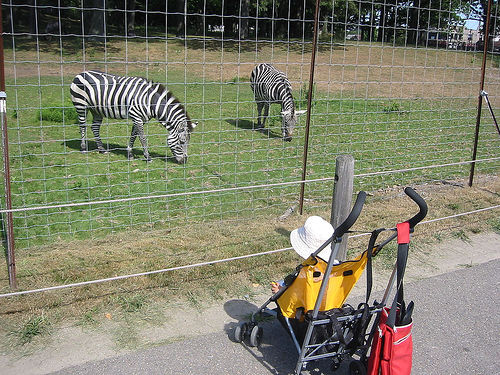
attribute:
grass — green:
[3, 73, 498, 256]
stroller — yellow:
[234, 184, 430, 373]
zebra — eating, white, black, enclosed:
[71, 72, 195, 165]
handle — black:
[401, 186, 427, 226]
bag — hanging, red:
[366, 222, 413, 374]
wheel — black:
[234, 322, 264, 347]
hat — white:
[290, 215, 341, 265]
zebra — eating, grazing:
[249, 63, 305, 142]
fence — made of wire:
[4, 6, 500, 275]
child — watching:
[268, 217, 339, 304]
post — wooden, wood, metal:
[298, 2, 323, 214]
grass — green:
[1, 25, 499, 326]